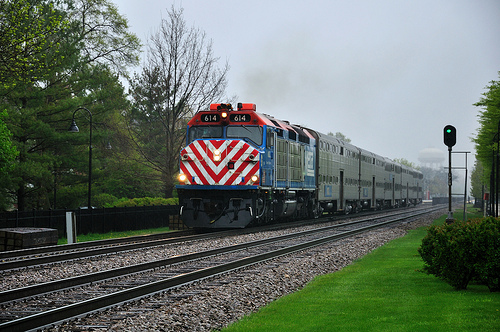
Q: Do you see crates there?
A: No, there are no crates.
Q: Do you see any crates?
A: No, there are no crates.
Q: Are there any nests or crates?
A: No, there are no crates or nests.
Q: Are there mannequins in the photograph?
A: No, there are no mannequins.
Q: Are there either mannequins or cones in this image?
A: No, there are no mannequins or cones.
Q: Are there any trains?
A: Yes, there is a train.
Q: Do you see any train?
A: Yes, there is a train.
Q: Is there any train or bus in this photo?
A: Yes, there is a train.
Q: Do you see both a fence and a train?
A: Yes, there are both a train and a fence.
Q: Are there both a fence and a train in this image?
A: Yes, there are both a train and a fence.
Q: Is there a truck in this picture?
A: No, there are no trucks.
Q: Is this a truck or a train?
A: This is a train.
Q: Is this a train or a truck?
A: This is a train.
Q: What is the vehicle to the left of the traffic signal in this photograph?
A: The vehicle is a train.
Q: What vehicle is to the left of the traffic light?
A: The vehicle is a train.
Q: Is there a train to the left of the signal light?
A: Yes, there is a train to the left of the signal light.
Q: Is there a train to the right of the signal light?
A: No, the train is to the left of the signal light.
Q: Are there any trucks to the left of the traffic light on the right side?
A: No, there is a train to the left of the signal light.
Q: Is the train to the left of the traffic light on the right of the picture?
A: Yes, the train is to the left of the traffic signal.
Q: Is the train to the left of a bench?
A: No, the train is to the left of the traffic signal.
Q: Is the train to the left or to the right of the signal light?
A: The train is to the left of the signal light.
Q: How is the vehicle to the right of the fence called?
A: The vehicle is a train.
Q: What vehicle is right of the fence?
A: The vehicle is a train.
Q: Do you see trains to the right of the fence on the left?
A: Yes, there is a train to the right of the fence.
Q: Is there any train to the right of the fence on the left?
A: Yes, there is a train to the right of the fence.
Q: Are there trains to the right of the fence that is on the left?
A: Yes, there is a train to the right of the fence.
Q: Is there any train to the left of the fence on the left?
A: No, the train is to the right of the fence.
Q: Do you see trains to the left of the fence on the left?
A: No, the train is to the right of the fence.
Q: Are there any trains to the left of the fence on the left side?
A: No, the train is to the right of the fence.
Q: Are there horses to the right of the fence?
A: No, there is a train to the right of the fence.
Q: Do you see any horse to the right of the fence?
A: No, there is a train to the right of the fence.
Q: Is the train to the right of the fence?
A: Yes, the train is to the right of the fence.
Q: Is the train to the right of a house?
A: No, the train is to the right of the fence.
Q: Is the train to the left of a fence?
A: No, the train is to the right of a fence.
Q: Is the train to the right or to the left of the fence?
A: The train is to the right of the fence.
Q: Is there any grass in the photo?
A: Yes, there is grass.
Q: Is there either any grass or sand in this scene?
A: Yes, there is grass.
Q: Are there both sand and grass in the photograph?
A: No, there is grass but no sand.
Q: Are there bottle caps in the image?
A: No, there are no bottle caps.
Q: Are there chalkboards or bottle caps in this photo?
A: No, there are no bottle caps or chalkboards.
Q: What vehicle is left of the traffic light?
A: The vehicle is a train car.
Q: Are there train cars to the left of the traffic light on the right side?
A: Yes, there is a train car to the left of the traffic signal.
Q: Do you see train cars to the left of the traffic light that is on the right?
A: Yes, there is a train car to the left of the traffic signal.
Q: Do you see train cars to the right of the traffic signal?
A: No, the train car is to the left of the traffic signal.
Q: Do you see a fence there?
A: Yes, there is a fence.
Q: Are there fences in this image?
A: Yes, there is a fence.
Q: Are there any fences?
A: Yes, there is a fence.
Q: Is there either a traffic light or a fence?
A: Yes, there is a fence.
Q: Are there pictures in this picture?
A: No, there are no pictures.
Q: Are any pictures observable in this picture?
A: No, there are no pictures.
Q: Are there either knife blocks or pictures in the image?
A: No, there are no pictures or knife blocks.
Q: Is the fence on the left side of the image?
A: Yes, the fence is on the left of the image.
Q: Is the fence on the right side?
A: No, the fence is on the left of the image.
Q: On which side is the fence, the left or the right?
A: The fence is on the left of the image.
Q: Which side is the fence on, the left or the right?
A: The fence is on the left of the image.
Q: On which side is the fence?
A: The fence is on the left of the image.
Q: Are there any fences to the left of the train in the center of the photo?
A: Yes, there is a fence to the left of the train.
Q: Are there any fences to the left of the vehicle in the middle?
A: Yes, there is a fence to the left of the train.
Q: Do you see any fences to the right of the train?
A: No, the fence is to the left of the train.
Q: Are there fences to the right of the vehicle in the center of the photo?
A: No, the fence is to the left of the train.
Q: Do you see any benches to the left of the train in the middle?
A: No, there is a fence to the left of the train.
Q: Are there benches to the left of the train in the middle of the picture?
A: No, there is a fence to the left of the train.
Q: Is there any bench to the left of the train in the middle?
A: No, there is a fence to the left of the train.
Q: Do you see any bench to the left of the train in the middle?
A: No, there is a fence to the left of the train.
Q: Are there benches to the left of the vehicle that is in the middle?
A: No, there is a fence to the left of the train.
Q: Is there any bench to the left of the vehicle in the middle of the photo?
A: No, there is a fence to the left of the train.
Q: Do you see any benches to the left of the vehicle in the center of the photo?
A: No, there is a fence to the left of the train.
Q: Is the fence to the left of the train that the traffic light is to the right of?
A: Yes, the fence is to the left of the train.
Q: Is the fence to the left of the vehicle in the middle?
A: Yes, the fence is to the left of the train.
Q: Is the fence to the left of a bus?
A: No, the fence is to the left of the train.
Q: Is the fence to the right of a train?
A: No, the fence is to the left of a train.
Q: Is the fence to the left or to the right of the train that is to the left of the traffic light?
A: The fence is to the left of the train.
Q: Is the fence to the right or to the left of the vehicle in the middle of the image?
A: The fence is to the left of the train.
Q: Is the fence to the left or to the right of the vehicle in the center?
A: The fence is to the left of the train.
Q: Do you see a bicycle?
A: No, there are no bicycles.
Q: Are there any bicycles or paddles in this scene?
A: No, there are no bicycles or paddles.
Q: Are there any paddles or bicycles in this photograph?
A: No, there are no bicycles or paddles.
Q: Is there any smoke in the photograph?
A: Yes, there is smoke.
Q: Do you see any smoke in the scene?
A: Yes, there is smoke.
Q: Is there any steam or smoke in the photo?
A: Yes, there is smoke.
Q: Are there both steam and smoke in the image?
A: No, there is smoke but no steam.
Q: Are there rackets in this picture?
A: No, there are no rackets.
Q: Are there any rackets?
A: No, there are no rackets.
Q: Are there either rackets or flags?
A: No, there are no rackets or flags.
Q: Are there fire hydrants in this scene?
A: No, there are no fire hydrants.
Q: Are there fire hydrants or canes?
A: No, there are no fire hydrants or canes.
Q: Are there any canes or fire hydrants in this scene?
A: No, there are no fire hydrants or canes.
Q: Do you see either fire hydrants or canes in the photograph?
A: No, there are no fire hydrants or canes.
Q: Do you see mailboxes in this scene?
A: No, there are no mailboxes.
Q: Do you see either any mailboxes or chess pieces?
A: No, there are no mailboxes or chess pieces.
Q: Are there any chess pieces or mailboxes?
A: No, there are no mailboxes or chess pieces.